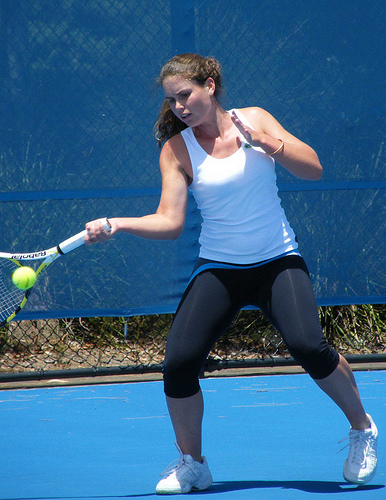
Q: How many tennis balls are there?
A: One.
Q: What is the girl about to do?
A: Hit the ball.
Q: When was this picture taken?
A: Daytime.